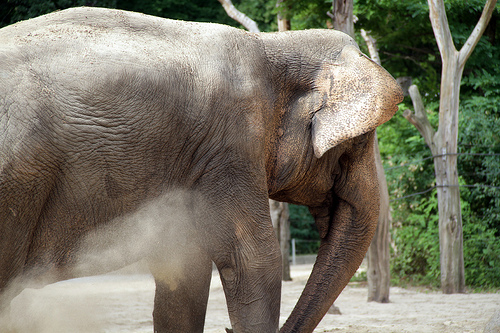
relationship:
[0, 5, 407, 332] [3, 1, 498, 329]
elephant in enclosure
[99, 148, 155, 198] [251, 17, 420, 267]
spot on side of elephant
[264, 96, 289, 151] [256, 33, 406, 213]
warts on elephant neck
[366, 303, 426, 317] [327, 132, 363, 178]
dirt on ground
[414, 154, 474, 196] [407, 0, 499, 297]
rope around tree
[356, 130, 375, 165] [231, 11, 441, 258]
eye in head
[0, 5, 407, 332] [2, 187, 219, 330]
elephant kicked up dust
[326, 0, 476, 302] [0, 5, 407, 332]
trees in front of elephant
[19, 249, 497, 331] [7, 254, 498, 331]
ground covered in dirt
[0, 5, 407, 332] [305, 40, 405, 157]
elephant has ear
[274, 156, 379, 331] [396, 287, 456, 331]
elephant's trunk kicking up dust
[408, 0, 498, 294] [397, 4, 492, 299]
bark of tree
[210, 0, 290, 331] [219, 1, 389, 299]
bark of tree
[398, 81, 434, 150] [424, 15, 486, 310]
branch of tree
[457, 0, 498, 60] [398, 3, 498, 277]
branch of tree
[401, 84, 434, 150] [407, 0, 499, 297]
branch of tree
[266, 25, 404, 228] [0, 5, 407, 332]
head of elephant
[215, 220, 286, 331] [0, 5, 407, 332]
leg of elephant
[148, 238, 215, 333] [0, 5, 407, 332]
leg of elephant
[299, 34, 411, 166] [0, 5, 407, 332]
ear of elephant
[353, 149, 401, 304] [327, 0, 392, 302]
leg of tree